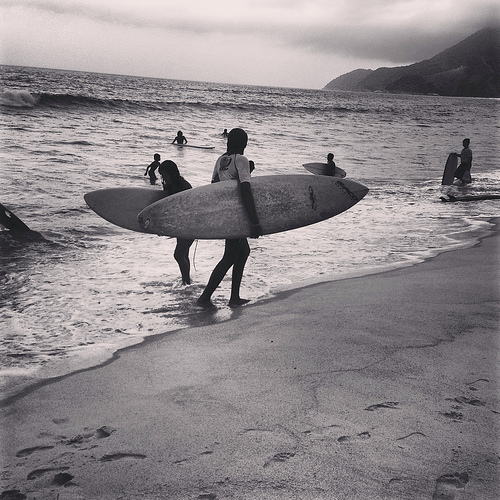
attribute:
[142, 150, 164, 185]
person — young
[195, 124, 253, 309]
person — barefoot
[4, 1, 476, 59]
sky — overcast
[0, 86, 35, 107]
wave — white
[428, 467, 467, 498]
footprint — large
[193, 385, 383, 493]
sand — small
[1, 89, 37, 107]
water — foamy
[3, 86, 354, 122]
wave — small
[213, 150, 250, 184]
swim shirt — white